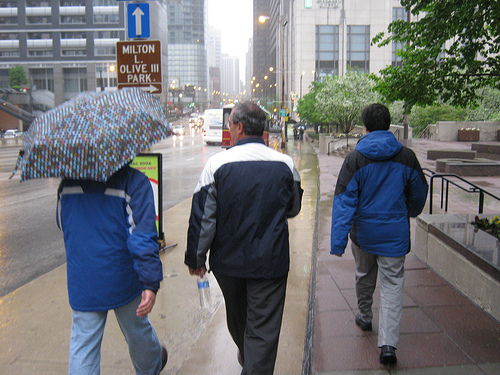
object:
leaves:
[366, 0, 500, 115]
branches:
[366, 0, 500, 116]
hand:
[188, 268, 206, 280]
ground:
[0, 146, 378, 375]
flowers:
[313, 74, 374, 120]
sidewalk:
[0, 124, 422, 375]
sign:
[115, 41, 163, 95]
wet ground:
[0, 107, 500, 375]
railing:
[422, 168, 500, 216]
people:
[54, 101, 426, 375]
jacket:
[55, 166, 163, 312]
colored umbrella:
[8, 86, 177, 183]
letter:
[123, 45, 130, 54]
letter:
[133, 45, 139, 54]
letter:
[142, 44, 149, 54]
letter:
[120, 64, 126, 74]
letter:
[135, 64, 141, 73]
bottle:
[197, 269, 211, 309]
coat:
[329, 130, 429, 257]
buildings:
[0, 0, 487, 132]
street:
[0, 108, 313, 374]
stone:
[427, 149, 476, 161]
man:
[185, 100, 304, 375]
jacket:
[184, 137, 303, 279]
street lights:
[170, 67, 276, 106]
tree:
[295, 64, 391, 136]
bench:
[426, 148, 478, 161]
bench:
[434, 158, 499, 177]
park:
[314, 114, 499, 321]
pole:
[114, 0, 162, 256]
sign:
[125, 2, 149, 38]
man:
[328, 103, 428, 367]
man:
[54, 165, 166, 375]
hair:
[361, 103, 391, 132]